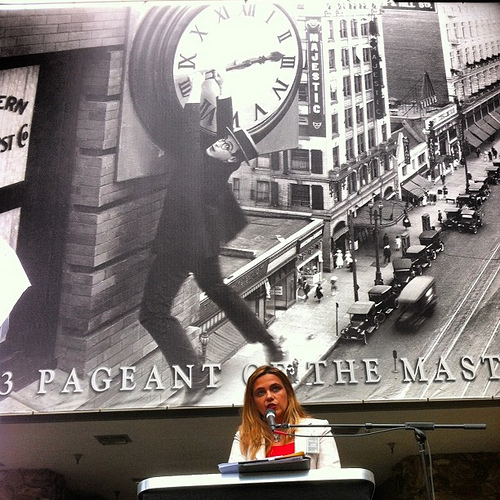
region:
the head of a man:
[194, 125, 274, 190]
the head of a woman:
[240, 357, 315, 430]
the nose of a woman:
[261, 381, 276, 406]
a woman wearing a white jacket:
[225, 340, 450, 466]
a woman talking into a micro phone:
[226, 326, 358, 447]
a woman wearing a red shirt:
[253, 432, 295, 462]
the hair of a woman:
[228, 330, 323, 456]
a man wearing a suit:
[128, 62, 324, 336]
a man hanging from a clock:
[118, 82, 330, 312]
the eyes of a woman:
[250, 373, 294, 406]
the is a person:
[10, 28, 346, 311]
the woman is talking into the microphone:
[225, 380, 383, 499]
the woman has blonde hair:
[237, 370, 331, 462]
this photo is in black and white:
[59, 35, 415, 247]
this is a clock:
[143, 19, 349, 149]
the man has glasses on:
[217, 122, 266, 159]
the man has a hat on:
[214, 120, 261, 157]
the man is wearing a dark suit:
[164, 150, 248, 340]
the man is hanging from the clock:
[157, 42, 309, 192]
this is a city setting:
[250, 30, 494, 262]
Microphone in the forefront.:
[262, 403, 283, 435]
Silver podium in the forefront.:
[141, 465, 377, 499]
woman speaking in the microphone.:
[223, 364, 348, 471]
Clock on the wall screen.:
[124, 5, 301, 154]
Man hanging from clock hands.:
[137, 65, 288, 400]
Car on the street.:
[343, 296, 380, 344]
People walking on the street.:
[297, 270, 342, 302]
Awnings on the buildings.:
[462, 105, 499, 149]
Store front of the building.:
[262, 260, 297, 327]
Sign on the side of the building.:
[303, 13, 331, 143]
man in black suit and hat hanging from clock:
[138, 69, 300, 404]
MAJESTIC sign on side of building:
[303, 28, 326, 138]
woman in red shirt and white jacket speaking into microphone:
[226, 365, 341, 467]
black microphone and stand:
[265, 408, 486, 499]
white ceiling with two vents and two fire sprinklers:
[1, 406, 498, 495]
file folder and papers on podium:
[216, 452, 311, 472]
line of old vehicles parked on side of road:
[338, 228, 445, 343]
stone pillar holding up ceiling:
[395, 452, 497, 499]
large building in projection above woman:
[381, 0, 498, 152]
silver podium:
[138, 467, 374, 499]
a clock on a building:
[97, 28, 395, 193]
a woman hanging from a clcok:
[91, 56, 368, 248]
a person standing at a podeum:
[179, 326, 380, 492]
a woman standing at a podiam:
[172, 344, 358, 489]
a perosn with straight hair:
[187, 326, 382, 496]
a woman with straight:
[212, 345, 354, 485]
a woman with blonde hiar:
[174, 344, 456, 496]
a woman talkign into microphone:
[222, 366, 337, 464]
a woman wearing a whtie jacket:
[235, 323, 393, 494]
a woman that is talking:
[207, 352, 474, 498]